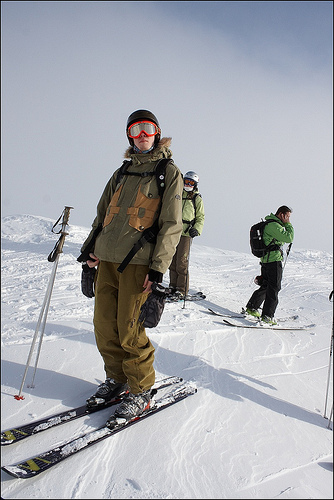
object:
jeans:
[93, 261, 155, 393]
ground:
[219, 254, 249, 273]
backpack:
[249, 218, 284, 258]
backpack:
[245, 215, 284, 260]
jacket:
[79, 136, 184, 270]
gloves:
[81, 263, 97, 299]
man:
[244, 205, 294, 326]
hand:
[282, 214, 288, 223]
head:
[275, 205, 293, 224]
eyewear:
[127, 122, 161, 139]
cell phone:
[282, 214, 286, 219]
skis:
[0, 383, 197, 480]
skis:
[0, 377, 198, 485]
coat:
[260, 212, 294, 264]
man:
[79, 110, 183, 395]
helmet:
[126, 109, 161, 140]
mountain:
[3, 210, 330, 492]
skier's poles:
[14, 205, 70, 400]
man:
[168, 172, 205, 295]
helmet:
[183, 171, 199, 183]